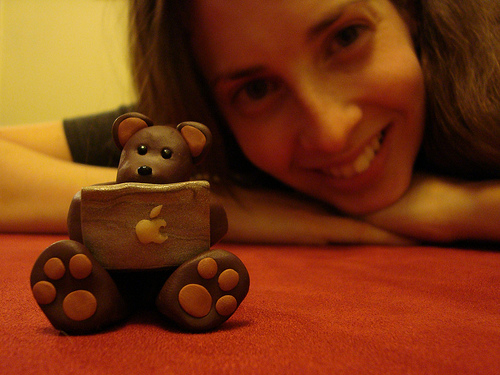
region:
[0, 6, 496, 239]
woman with large hair smiling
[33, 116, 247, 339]
little ceramic teddy bear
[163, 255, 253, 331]
right foot of teddy bear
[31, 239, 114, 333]
left foot of ceramic teddy bear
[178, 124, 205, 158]
small right ceramic ear of teddy bear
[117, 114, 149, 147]
small left ceramic ear of teddy bear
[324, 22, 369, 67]
little right black eye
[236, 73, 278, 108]
little black left eye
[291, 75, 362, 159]
big nose of girl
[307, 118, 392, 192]
big mouth with white teeths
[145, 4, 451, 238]
the head of a woman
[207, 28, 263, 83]
the eyebrow of a woman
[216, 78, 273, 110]
the right eye of a woman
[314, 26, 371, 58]
the left eye of a woman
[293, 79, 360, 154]
the nose of a woman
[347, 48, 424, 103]
the cheek of a woman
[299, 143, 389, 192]
the mouth of a woman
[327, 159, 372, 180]
the teeth of a woman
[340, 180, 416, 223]
the chin of a woman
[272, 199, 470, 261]
the hands of a woman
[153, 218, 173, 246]
The bited part of an apple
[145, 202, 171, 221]
A leaf of an apple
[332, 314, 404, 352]
A smooth red surface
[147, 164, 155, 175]
Tip of the bears black nose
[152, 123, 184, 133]
Top of the bears' brown head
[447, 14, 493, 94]
A brown and dry hair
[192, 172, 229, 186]
Beads of the bracelet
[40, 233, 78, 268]
Tip of the bears' big feat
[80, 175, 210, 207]
Top of the brown tablet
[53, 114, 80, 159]
Hem of the black shirt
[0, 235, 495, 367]
fuzzy red fabric under mouse feet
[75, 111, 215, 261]
brown mouse using laptop on lap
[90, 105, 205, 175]
pink ears bordered in brown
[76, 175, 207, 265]
wavy edge on top cover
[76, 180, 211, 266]
famous logo on laptop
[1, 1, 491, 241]
woman in front of yellow wall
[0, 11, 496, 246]
both hands positioned under chin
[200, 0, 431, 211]
woman smiling and showing upper teeth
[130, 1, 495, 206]
woman with brown hair and brown eyes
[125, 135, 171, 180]
beady eyes over upturned black nose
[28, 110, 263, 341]
small bear figurine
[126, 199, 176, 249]
small apple logo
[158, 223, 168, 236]
bite taken out of the apple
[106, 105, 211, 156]
two small ears on the top of the head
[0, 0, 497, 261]
woman resting her face on her arms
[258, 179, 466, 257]
one hand on top of the other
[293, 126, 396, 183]
smile on the face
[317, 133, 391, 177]
a row of white teeth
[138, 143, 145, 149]
small glint in the eye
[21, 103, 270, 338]
bear holding an Apple laptop